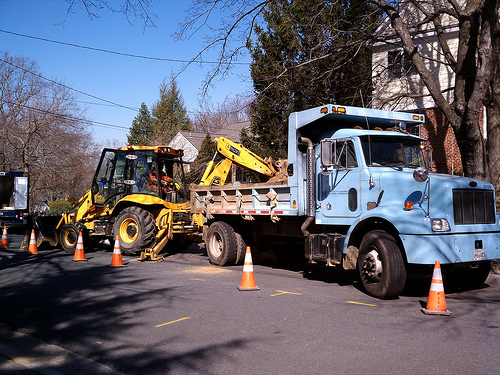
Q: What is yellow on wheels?
A: Construction machinery.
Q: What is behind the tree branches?
A: A house.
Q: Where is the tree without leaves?
A: Behind truck.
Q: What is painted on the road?
A: Orange lines.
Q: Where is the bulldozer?
A: On street.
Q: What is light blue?
A: Construction truck.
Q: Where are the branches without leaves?
A: Above bulldozer.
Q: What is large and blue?
A: Dump truck.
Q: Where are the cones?
A: Next to the truck.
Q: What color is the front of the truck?
A: Blue.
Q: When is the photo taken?
A: During the day.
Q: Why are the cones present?
A: Construction is occurring.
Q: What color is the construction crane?
A: Yellow.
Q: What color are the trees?
A: Green.